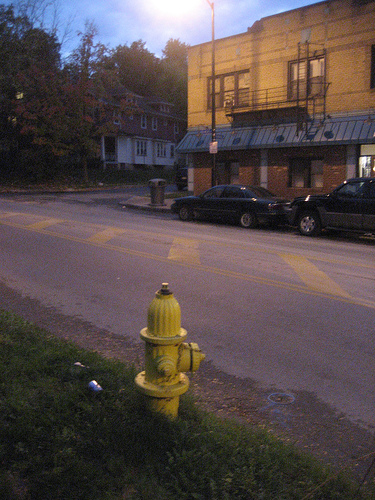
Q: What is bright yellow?
A: Hydrant.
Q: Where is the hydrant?
A: Side of road.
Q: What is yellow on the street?
A: Lines.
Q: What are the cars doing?
A: Parked.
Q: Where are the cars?
A: Side of road.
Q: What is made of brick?
A: Building.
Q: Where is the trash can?
A: Corner.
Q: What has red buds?
A: Tree.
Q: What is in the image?
A: Fire hydrant.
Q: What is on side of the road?
A: Grass.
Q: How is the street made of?
A: Asphalt.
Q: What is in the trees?
A: House.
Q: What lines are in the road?
A: Yellow lines.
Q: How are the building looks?
A: Brick.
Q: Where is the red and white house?
A: Behind the brick building.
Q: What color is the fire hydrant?
A: Yellow.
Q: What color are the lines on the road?
A: Yellow.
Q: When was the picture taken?
A: Dusk.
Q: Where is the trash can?
A: On the corner.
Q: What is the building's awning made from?
A: Metal.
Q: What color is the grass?
A: Green.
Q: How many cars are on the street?
A: Two.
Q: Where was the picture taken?
A: By the side of the road.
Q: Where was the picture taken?
A: By the fire hydrant.